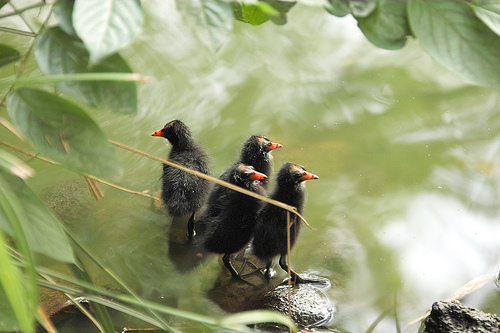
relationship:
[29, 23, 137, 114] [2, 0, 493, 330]
leaf on plant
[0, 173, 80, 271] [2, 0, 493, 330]
green leaf on plant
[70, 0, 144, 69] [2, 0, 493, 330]
green leaf on plant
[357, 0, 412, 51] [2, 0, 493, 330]
leaf on plant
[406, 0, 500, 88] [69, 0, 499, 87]
green leaf on plant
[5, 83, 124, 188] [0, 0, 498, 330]
green leaf on tree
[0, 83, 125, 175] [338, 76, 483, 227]
green leaf on tree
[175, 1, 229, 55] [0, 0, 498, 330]
green leaf on tree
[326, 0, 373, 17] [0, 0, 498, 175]
leaf on tree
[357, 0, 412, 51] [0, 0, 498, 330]
leaf on tree